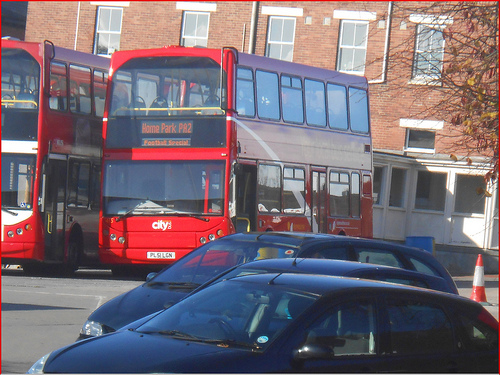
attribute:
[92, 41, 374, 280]
red bus — two story, parked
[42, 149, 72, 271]
door — black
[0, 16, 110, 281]
bus — red, parked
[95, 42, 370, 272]
bus — red, double decker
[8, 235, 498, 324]
street — city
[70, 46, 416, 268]
buses — red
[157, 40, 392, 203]
bus — two levels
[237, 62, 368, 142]
windows — side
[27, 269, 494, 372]
car — black, three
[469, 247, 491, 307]
cone — orange and white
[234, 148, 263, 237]
door — open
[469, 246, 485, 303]
cone — safety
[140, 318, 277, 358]
wipers — windshield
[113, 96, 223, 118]
rail — yellow